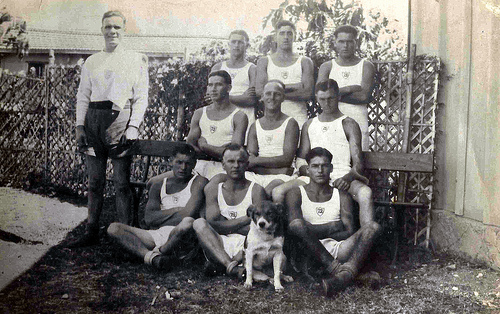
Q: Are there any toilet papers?
A: No, there are no toilet papers.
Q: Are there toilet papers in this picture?
A: No, there are no toilet papers.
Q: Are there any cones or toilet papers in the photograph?
A: No, there are no toilet papers or cones.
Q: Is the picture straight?
A: Yes, the picture is straight.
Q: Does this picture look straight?
A: Yes, the picture is straight.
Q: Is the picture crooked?
A: No, the picture is straight.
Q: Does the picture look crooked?
A: No, the picture is straight.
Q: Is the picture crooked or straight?
A: The picture is straight.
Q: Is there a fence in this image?
A: Yes, there is a fence.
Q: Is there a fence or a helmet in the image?
A: Yes, there is a fence.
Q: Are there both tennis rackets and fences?
A: No, there is a fence but no rackets.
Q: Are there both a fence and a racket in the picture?
A: No, there is a fence but no rackets.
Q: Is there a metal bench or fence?
A: Yes, there is a metal fence.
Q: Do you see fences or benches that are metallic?
A: Yes, the fence is metallic.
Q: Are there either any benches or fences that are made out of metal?
A: Yes, the fence is made of metal.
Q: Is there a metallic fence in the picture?
A: Yes, there is a metal fence.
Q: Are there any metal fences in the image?
A: Yes, there is a metal fence.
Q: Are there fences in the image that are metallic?
A: Yes, there is a fence that is metallic.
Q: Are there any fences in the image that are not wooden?
A: Yes, there is a metallic fence.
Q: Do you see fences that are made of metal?
A: Yes, there is a fence that is made of metal.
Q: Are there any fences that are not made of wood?
A: Yes, there is a fence that is made of metal.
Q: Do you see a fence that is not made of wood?
A: Yes, there is a fence that is made of metal.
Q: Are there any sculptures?
A: No, there are no sculptures.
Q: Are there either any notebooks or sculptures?
A: No, there are no sculptures or notebooks.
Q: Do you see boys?
A: No, there are no boys.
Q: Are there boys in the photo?
A: No, there are no boys.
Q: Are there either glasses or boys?
A: No, there are no boys or glasses.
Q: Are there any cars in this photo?
A: No, there are no cars.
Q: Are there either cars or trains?
A: No, there are no cars or trains.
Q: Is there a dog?
A: Yes, there is a dog.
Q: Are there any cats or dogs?
A: Yes, there is a dog.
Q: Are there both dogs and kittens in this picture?
A: No, there is a dog but no kittens.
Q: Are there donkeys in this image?
A: No, there are no donkeys.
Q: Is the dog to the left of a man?
A: No, the dog is to the right of a man.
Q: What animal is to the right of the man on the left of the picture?
A: The animal is a dog.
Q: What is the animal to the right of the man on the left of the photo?
A: The animal is a dog.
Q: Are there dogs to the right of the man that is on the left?
A: Yes, there is a dog to the right of the man.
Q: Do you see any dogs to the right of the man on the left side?
A: Yes, there is a dog to the right of the man.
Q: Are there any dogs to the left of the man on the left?
A: No, the dog is to the right of the man.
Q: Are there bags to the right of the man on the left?
A: No, there is a dog to the right of the man.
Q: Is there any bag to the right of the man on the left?
A: No, there is a dog to the right of the man.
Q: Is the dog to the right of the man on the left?
A: Yes, the dog is to the right of the man.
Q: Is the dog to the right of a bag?
A: No, the dog is to the right of the man.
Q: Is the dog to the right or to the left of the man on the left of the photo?
A: The dog is to the right of the man.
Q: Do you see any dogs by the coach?
A: Yes, there is a dog by the coach.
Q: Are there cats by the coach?
A: No, there is a dog by the coach.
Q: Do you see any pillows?
A: No, there are no pillows.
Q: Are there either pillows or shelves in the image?
A: No, there are no pillows or shelves.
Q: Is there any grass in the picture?
A: Yes, there is grass.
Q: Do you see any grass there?
A: Yes, there is grass.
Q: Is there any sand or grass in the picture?
A: Yes, there is grass.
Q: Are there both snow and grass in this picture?
A: No, there is grass but no snow.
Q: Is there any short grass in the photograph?
A: Yes, there is short grass.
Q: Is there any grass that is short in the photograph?
A: Yes, there is short grass.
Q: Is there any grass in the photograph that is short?
A: Yes, there is grass that is short.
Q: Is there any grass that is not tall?
A: Yes, there is short grass.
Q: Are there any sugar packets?
A: No, there are no sugar packets.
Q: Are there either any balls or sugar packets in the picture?
A: No, there are no sugar packets or balls.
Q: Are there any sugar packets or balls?
A: No, there are no sugar packets or balls.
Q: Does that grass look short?
A: Yes, the grass is short.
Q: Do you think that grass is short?
A: Yes, the grass is short.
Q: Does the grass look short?
A: Yes, the grass is short.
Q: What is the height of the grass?
A: The grass is short.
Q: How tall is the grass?
A: The grass is short.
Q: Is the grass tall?
A: No, the grass is short.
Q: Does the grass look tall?
A: No, the grass is short.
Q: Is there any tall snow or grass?
A: No, there is grass but it is short.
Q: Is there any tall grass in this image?
A: No, there is grass but it is short.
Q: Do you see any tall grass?
A: No, there is grass but it is short.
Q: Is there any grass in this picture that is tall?
A: No, there is grass but it is short.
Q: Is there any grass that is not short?
A: No, there is grass but it is short.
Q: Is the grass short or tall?
A: The grass is short.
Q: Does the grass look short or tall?
A: The grass is short.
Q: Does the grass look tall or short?
A: The grass is short.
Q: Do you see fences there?
A: Yes, there is a fence.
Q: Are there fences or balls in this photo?
A: Yes, there is a fence.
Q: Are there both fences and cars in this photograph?
A: No, there is a fence but no cars.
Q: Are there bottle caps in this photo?
A: No, there are no bottle caps.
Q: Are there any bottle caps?
A: No, there are no bottle caps.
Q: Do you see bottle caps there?
A: No, there are no bottle caps.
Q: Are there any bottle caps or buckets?
A: No, there are no bottle caps or buckets.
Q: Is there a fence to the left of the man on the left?
A: Yes, there is a fence to the left of the man.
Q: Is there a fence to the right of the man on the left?
A: No, the fence is to the left of the man.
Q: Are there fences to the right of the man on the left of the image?
A: No, the fence is to the left of the man.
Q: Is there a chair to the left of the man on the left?
A: No, there is a fence to the left of the man.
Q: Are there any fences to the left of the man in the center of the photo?
A: Yes, there is a fence to the left of the man.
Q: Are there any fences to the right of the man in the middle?
A: No, the fence is to the left of the man.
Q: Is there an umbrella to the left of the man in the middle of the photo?
A: No, there is a fence to the left of the man.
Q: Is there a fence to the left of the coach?
A: Yes, there is a fence to the left of the coach.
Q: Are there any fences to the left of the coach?
A: Yes, there is a fence to the left of the coach.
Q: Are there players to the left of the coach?
A: No, there is a fence to the left of the coach.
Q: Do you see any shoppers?
A: No, there are no shoppers.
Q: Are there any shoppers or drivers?
A: No, there are no shoppers or drivers.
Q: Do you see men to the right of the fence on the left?
A: Yes, there is a man to the right of the fence.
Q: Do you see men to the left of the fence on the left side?
A: No, the man is to the right of the fence.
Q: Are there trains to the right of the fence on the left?
A: No, there is a man to the right of the fence.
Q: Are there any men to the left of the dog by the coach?
A: Yes, there is a man to the left of the dog.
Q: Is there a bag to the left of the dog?
A: No, there is a man to the left of the dog.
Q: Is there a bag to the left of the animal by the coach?
A: No, there is a man to the left of the dog.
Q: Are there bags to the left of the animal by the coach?
A: No, there is a man to the left of the dog.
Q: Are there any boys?
A: No, there are no boys.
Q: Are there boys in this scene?
A: No, there are no boys.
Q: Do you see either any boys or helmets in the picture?
A: No, there are no boys or helmets.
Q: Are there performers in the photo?
A: No, there are no performers.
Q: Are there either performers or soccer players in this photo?
A: No, there are no performers or soccer players.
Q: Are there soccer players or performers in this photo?
A: No, there are no performers or soccer players.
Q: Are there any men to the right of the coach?
A: Yes, there is a man to the right of the coach.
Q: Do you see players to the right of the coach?
A: No, there is a man to the right of the coach.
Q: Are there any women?
A: No, there are no women.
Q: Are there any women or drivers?
A: No, there are no women or drivers.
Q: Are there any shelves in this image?
A: No, there are no shelves.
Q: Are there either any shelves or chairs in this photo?
A: No, there are no shelves or chairs.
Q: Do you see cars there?
A: No, there are no cars.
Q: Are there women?
A: No, there are no women.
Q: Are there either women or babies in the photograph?
A: No, there are no women or babies.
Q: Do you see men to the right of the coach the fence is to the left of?
A: Yes, there is a man to the right of the coach.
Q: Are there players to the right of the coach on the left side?
A: No, there is a man to the right of the coach.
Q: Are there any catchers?
A: No, there are no catchers.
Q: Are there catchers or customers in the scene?
A: No, there are no catchers or customers.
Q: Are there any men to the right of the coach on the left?
A: Yes, there is a man to the right of the coach.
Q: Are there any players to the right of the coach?
A: No, there is a man to the right of the coach.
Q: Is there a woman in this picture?
A: No, there are no women.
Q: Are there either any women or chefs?
A: No, there are no women or chefs.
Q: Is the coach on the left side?
A: Yes, the coach is on the left of the image.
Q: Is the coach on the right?
A: No, the coach is on the left of the image.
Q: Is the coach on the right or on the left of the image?
A: The coach is on the left of the image.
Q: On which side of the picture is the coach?
A: The coach is on the left of the image.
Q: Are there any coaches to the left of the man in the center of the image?
A: Yes, there is a coach to the left of the man.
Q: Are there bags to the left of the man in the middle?
A: No, there is a coach to the left of the man.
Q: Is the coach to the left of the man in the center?
A: Yes, the coach is to the left of the man.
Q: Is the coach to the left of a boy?
A: No, the coach is to the left of the man.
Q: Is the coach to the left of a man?
A: Yes, the coach is to the left of a man.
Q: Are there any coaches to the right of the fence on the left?
A: Yes, there is a coach to the right of the fence.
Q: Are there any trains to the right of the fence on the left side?
A: No, there is a coach to the right of the fence.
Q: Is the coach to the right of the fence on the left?
A: Yes, the coach is to the right of the fence.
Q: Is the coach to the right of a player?
A: No, the coach is to the right of the fence.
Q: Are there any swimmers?
A: No, there are no swimmers.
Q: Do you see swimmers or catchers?
A: No, there are no swimmers or catchers.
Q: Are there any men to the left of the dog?
A: Yes, there is a man to the left of the dog.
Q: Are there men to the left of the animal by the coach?
A: Yes, there is a man to the left of the dog.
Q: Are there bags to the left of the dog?
A: No, there is a man to the left of the dog.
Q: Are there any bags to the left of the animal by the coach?
A: No, there is a man to the left of the dog.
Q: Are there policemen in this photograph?
A: No, there are no policemen.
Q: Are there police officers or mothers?
A: No, there are no police officers or mothers.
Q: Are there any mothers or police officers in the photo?
A: No, there are no police officers or mothers.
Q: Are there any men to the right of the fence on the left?
A: Yes, there is a man to the right of the fence.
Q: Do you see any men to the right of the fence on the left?
A: Yes, there is a man to the right of the fence.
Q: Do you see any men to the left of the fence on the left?
A: No, the man is to the right of the fence.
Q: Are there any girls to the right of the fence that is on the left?
A: No, there is a man to the right of the fence.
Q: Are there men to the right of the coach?
A: Yes, there is a man to the right of the coach.